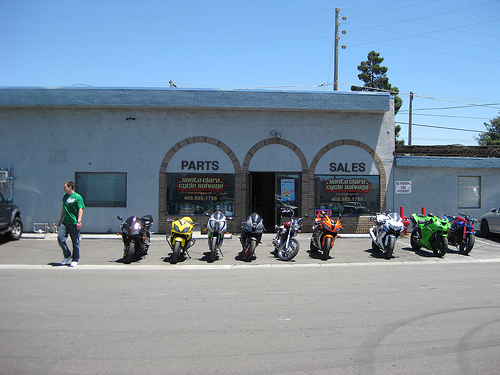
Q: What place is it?
A: It is a street.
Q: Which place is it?
A: It is a street.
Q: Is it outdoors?
A: Yes, it is outdoors.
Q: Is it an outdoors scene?
A: Yes, it is outdoors.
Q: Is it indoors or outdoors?
A: It is outdoors.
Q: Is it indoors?
A: No, it is outdoors.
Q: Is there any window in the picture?
A: Yes, there is a window.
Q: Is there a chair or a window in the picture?
A: Yes, there is a window.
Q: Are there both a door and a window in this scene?
A: Yes, there are both a window and a door.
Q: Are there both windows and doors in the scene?
A: Yes, there are both a window and a door.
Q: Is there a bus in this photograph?
A: No, there are no buses.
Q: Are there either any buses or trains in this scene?
A: No, there are no buses or trains.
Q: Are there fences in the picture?
A: No, there are no fences.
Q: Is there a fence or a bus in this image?
A: No, there are no fences or buses.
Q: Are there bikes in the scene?
A: Yes, there is a bike.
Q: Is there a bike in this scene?
A: Yes, there is a bike.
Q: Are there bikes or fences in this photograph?
A: Yes, there is a bike.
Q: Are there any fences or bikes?
A: Yes, there is a bike.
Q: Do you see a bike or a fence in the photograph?
A: Yes, there is a bike.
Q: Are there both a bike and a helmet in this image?
A: No, there is a bike but no helmets.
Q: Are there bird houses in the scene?
A: No, there are no bird houses.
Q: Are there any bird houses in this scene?
A: No, there are no bird houses.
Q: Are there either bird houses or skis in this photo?
A: No, there are no bird houses or skis.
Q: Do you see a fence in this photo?
A: No, there are no fences.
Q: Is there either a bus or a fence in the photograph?
A: No, there are no fences or buses.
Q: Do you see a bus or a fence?
A: No, there are no fences or buses.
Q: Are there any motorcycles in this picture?
A: Yes, there is a motorcycle.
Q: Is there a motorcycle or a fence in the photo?
A: Yes, there is a motorcycle.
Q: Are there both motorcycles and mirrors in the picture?
A: No, there is a motorcycle but no mirrors.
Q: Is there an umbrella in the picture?
A: No, there are no umbrellas.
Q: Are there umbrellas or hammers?
A: No, there are no umbrellas or hammers.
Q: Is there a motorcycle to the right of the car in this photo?
A: Yes, there is a motorcycle to the right of the car.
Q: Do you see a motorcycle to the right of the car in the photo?
A: Yes, there is a motorcycle to the right of the car.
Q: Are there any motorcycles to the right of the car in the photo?
A: Yes, there is a motorcycle to the right of the car.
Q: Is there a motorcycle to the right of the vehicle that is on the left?
A: Yes, there is a motorcycle to the right of the car.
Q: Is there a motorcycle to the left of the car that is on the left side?
A: No, the motorcycle is to the right of the car.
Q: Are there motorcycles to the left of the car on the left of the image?
A: No, the motorcycle is to the right of the car.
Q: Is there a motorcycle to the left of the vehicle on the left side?
A: No, the motorcycle is to the right of the car.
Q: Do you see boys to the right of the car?
A: No, there is a motorcycle to the right of the car.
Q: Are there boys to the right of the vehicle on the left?
A: No, there is a motorcycle to the right of the car.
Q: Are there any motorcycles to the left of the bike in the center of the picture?
A: Yes, there is a motorcycle to the left of the bike.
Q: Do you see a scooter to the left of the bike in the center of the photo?
A: No, there is a motorcycle to the left of the bike.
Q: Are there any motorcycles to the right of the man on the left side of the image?
A: Yes, there is a motorcycle to the right of the man.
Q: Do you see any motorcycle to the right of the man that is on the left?
A: Yes, there is a motorcycle to the right of the man.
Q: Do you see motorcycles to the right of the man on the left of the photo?
A: Yes, there is a motorcycle to the right of the man.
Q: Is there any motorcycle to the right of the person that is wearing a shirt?
A: Yes, there is a motorcycle to the right of the man.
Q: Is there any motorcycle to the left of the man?
A: No, the motorcycle is to the right of the man.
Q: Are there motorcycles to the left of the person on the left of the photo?
A: No, the motorcycle is to the right of the man.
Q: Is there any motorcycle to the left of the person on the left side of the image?
A: No, the motorcycle is to the right of the man.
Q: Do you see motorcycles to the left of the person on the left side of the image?
A: No, the motorcycle is to the right of the man.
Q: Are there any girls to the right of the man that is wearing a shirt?
A: No, there is a motorcycle to the right of the man.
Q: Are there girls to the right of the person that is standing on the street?
A: No, there is a motorcycle to the right of the man.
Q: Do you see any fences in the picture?
A: No, there are no fences.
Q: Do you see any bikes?
A: Yes, there is a bike.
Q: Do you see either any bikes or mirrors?
A: Yes, there is a bike.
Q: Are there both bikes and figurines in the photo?
A: No, there is a bike but no figurines.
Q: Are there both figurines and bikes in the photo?
A: No, there is a bike but no figurines.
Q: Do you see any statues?
A: No, there are no statues.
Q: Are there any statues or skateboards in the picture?
A: No, there are no statues or skateboards.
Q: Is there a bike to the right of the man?
A: Yes, there is a bike to the right of the man.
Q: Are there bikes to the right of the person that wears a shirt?
A: Yes, there is a bike to the right of the man.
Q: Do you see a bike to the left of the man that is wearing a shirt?
A: No, the bike is to the right of the man.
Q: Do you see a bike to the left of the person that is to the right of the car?
A: No, the bike is to the right of the man.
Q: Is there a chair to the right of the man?
A: No, there is a bike to the right of the man.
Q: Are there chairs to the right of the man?
A: No, there is a bike to the right of the man.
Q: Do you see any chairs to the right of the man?
A: No, there is a bike to the right of the man.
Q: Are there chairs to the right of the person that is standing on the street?
A: No, there is a bike to the right of the man.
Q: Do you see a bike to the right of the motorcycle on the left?
A: Yes, there is a bike to the right of the motorcycle.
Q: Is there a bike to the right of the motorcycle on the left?
A: Yes, there is a bike to the right of the motorcycle.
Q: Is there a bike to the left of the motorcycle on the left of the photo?
A: No, the bike is to the right of the motorcycle.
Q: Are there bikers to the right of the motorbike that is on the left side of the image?
A: No, there is a bike to the right of the motorcycle.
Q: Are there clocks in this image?
A: No, there are no clocks.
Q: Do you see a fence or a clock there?
A: No, there are no clocks or fences.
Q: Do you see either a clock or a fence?
A: No, there are no clocks or fences.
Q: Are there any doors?
A: Yes, there is a door.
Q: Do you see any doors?
A: Yes, there is a door.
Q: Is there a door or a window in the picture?
A: Yes, there is a door.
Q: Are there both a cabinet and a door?
A: No, there is a door but no cabinets.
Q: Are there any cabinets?
A: No, there are no cabinets.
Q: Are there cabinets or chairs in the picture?
A: No, there are no cabinets or chairs.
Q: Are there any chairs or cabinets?
A: No, there are no cabinets or chairs.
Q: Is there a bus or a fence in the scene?
A: No, there are no fences or buses.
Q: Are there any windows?
A: Yes, there is a window.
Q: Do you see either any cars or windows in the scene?
A: Yes, there is a window.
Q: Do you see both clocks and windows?
A: No, there is a window but no clocks.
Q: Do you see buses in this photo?
A: No, there are no buses.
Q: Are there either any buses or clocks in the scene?
A: No, there are no buses or clocks.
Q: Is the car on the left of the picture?
A: Yes, the car is on the left of the image.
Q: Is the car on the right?
A: No, the car is on the left of the image.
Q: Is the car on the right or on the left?
A: The car is on the left of the image.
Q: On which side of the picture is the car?
A: The car is on the left of the image.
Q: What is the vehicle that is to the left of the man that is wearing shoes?
A: The vehicle is a car.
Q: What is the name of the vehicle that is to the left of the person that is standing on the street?
A: The vehicle is a car.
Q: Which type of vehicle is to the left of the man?
A: The vehicle is a car.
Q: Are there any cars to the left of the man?
A: Yes, there is a car to the left of the man.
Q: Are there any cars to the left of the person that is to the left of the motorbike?
A: Yes, there is a car to the left of the man.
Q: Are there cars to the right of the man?
A: No, the car is to the left of the man.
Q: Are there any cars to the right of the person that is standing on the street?
A: No, the car is to the left of the man.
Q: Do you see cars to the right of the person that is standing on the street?
A: No, the car is to the left of the man.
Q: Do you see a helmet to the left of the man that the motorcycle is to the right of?
A: No, there is a car to the left of the man.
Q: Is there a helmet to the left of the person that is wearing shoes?
A: No, there is a car to the left of the man.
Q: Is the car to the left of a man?
A: Yes, the car is to the left of a man.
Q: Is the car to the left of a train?
A: No, the car is to the left of a man.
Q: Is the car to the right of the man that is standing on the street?
A: No, the car is to the left of the man.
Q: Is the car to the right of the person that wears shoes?
A: No, the car is to the left of the man.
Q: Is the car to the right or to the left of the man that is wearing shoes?
A: The car is to the left of the man.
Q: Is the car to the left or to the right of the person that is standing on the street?
A: The car is to the left of the man.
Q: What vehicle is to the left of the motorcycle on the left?
A: The vehicle is a car.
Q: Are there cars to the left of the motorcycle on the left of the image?
A: Yes, there is a car to the left of the motorcycle.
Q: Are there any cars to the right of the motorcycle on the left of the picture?
A: No, the car is to the left of the motorbike.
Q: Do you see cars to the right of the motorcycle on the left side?
A: No, the car is to the left of the motorbike.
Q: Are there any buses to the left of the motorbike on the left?
A: No, there is a car to the left of the motorbike.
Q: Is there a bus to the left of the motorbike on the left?
A: No, there is a car to the left of the motorbike.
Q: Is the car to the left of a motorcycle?
A: Yes, the car is to the left of a motorcycle.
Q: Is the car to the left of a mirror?
A: No, the car is to the left of a motorcycle.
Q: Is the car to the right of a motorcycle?
A: No, the car is to the left of a motorcycle.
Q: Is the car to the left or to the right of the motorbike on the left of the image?
A: The car is to the left of the motorcycle.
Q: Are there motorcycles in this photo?
A: Yes, there is a motorcycle.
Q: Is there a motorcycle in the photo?
A: Yes, there is a motorcycle.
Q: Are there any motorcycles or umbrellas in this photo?
A: Yes, there is a motorcycle.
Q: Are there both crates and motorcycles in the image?
A: No, there is a motorcycle but no crates.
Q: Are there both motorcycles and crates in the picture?
A: No, there is a motorcycle but no crates.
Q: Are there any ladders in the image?
A: No, there are no ladders.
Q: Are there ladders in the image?
A: No, there are no ladders.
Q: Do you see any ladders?
A: No, there are no ladders.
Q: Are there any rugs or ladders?
A: No, there are no ladders or rugs.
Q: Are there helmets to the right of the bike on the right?
A: No, there is a motorcycle to the right of the bike.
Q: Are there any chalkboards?
A: No, there are no chalkboards.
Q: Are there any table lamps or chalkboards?
A: No, there are no chalkboards or table lamps.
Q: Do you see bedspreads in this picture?
A: No, there are no bedspreads.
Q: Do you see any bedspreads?
A: No, there are no bedspreads.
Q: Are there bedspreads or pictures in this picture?
A: No, there are no bedspreads or pictures.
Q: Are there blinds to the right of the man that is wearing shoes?
A: Yes, there are blinds to the right of the man.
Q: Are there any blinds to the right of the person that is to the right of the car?
A: Yes, there are blinds to the right of the man.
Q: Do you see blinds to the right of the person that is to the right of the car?
A: Yes, there are blinds to the right of the man.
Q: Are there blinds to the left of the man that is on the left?
A: No, the blinds are to the right of the man.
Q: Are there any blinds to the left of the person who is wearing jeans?
A: No, the blinds are to the right of the man.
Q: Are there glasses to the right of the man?
A: No, there are blinds to the right of the man.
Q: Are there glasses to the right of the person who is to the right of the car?
A: No, there are blinds to the right of the man.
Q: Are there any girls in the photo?
A: No, there are no girls.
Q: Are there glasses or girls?
A: No, there are no girls or glasses.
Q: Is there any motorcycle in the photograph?
A: Yes, there is a motorcycle.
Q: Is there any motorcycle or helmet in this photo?
A: Yes, there is a motorcycle.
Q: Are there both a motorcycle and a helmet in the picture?
A: No, there is a motorcycle but no helmets.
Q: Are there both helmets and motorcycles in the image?
A: No, there is a motorcycle but no helmets.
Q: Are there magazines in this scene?
A: No, there are no magazines.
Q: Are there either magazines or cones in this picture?
A: No, there are no magazines or cones.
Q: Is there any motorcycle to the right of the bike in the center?
A: Yes, there is a motorcycle to the right of the bike.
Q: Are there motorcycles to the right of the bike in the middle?
A: Yes, there is a motorcycle to the right of the bike.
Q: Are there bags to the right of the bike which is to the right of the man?
A: No, there is a motorcycle to the right of the bike.